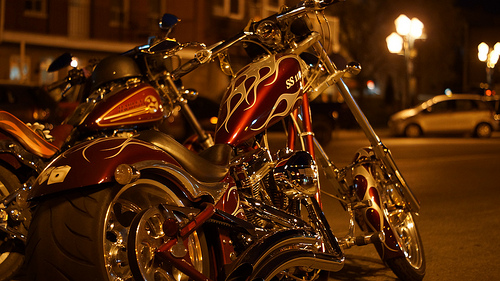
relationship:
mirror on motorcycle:
[44, 51, 79, 73] [2, 12, 213, 279]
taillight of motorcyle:
[114, 161, 185, 211] [17, 1, 432, 279]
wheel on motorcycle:
[19, 155, 224, 280] [21, 0, 427, 281]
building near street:
[0, 0, 342, 105] [323, 136, 499, 279]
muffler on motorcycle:
[219, 200, 348, 278] [21, 0, 427, 281]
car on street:
[388, 94, 499, 140] [333, 118, 498, 278]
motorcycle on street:
[21, 0, 427, 281] [323, 136, 499, 279]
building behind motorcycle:
[4, 2, 334, 113] [21, 0, 427, 281]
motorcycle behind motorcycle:
[0, 12, 227, 281] [21, 0, 427, 281]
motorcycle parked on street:
[21, 0, 427, 281] [323, 136, 499, 279]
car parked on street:
[390, 90, 499, 141] [424, 138, 484, 279]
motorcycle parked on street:
[37, 6, 444, 266] [2, 91, 477, 252]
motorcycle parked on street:
[6, 26, 239, 271] [2, 91, 477, 252]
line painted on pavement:
[378, 147, 498, 167] [267, 124, 498, 279]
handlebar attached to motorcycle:
[147, 0, 341, 81] [89, 2, 426, 280]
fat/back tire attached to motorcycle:
[32, 172, 210, 279] [21, 0, 427, 281]